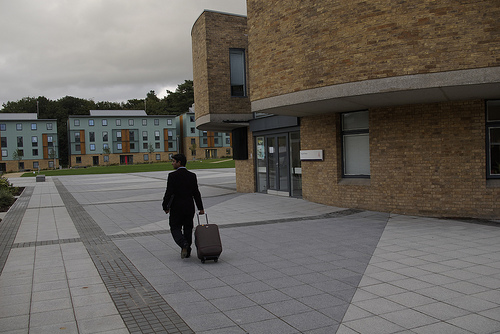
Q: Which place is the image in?
A: It is at the sidewalk.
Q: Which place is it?
A: It is a sidewalk.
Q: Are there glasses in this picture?
A: No, there are no glasses.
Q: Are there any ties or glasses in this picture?
A: No, there are no glasses or ties.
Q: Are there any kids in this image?
A: No, there are no kids.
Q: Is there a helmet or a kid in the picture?
A: No, there are no children or helmets.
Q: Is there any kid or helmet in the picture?
A: No, there are no children or helmets.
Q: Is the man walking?
A: Yes, the man is walking.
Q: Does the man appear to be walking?
A: Yes, the man is walking.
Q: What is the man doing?
A: The man is walking.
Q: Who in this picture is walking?
A: The man is walking.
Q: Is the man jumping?
A: No, the man is walking.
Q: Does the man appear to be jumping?
A: No, the man is walking.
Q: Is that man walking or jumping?
A: The man is walking.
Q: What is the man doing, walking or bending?
A: The man is walking.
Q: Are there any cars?
A: No, there are no cars.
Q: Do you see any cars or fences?
A: No, there are no cars or fences.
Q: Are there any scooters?
A: No, there are no scooters.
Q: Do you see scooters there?
A: No, there are no scooters.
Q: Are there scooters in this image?
A: No, there are no scooters.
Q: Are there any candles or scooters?
A: No, there are no scooters or candles.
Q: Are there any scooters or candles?
A: No, there are no scooters or candles.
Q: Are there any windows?
A: Yes, there is a window.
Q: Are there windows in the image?
A: Yes, there is a window.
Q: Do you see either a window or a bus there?
A: Yes, there is a window.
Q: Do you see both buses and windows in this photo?
A: No, there is a window but no buses.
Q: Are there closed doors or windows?
A: Yes, there is a closed window.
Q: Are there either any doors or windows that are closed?
A: Yes, the window is closed.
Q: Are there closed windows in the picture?
A: Yes, there is a closed window.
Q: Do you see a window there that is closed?
A: Yes, there is a window that is closed.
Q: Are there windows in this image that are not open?
A: Yes, there is an closed window.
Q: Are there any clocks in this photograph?
A: No, there are no clocks.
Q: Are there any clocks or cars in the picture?
A: No, there are no clocks or cars.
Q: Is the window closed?
A: Yes, the window is closed.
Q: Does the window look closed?
A: Yes, the window is closed.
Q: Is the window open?
A: No, the window is closed.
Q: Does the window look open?
A: No, the window is closed.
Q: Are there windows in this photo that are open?
A: No, there is a window but it is closed.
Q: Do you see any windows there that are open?
A: No, there is a window but it is closed.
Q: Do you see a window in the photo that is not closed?
A: No, there is a window but it is closed.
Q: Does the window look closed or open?
A: The window is closed.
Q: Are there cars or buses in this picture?
A: No, there are no cars or buses.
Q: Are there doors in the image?
A: Yes, there is a door.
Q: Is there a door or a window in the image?
A: Yes, there is a door.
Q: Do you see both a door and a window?
A: Yes, there are both a door and a window.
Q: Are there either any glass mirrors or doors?
A: Yes, there is a glass door.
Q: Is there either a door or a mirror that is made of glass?
A: Yes, the door is made of glass.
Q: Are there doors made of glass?
A: Yes, there is a door that is made of glass.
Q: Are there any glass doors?
A: Yes, there is a door that is made of glass.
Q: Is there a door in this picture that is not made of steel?
A: Yes, there is a door that is made of glass.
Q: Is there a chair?
A: No, there are no chairs.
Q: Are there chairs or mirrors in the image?
A: No, there are no chairs or mirrors.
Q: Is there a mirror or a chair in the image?
A: No, there are no chairs or mirrors.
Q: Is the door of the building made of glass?
A: Yes, the door is made of glass.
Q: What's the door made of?
A: The door is made of glass.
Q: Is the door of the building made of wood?
A: No, the door is made of glass.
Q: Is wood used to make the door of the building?
A: No, the door is made of glass.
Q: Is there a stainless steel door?
A: No, there is a door but it is made of glass.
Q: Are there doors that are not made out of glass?
A: No, there is a door but it is made of glass.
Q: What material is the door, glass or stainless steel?
A: The door is made of glass.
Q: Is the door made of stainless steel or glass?
A: The door is made of glass.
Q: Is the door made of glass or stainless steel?
A: The door is made of glass.